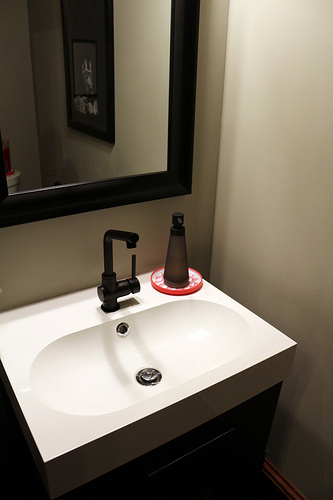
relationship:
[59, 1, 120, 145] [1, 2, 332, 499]
picture hanging on wall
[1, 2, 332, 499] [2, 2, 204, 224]
wall reflected in mirror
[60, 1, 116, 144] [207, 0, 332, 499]
picture on wall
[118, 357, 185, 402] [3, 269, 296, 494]
hole in sink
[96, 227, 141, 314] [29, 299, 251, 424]
faucet above sink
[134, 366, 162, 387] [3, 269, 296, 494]
draine in sink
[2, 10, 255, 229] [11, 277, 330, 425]
mirror above sink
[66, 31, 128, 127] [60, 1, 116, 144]
reflection of a picture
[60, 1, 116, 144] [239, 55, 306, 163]
picture on wall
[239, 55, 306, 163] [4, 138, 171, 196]
wall in mirror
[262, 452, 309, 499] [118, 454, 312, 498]
moulding on floor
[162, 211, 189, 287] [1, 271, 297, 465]
bottle on counter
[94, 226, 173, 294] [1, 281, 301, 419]
faucet on sink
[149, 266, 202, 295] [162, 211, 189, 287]
coaster under bottle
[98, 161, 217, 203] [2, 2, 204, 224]
rim on mirror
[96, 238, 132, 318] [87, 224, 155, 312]
pipe on faucet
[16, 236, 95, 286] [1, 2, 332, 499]
paint on wall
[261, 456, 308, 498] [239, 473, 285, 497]
trim on floor